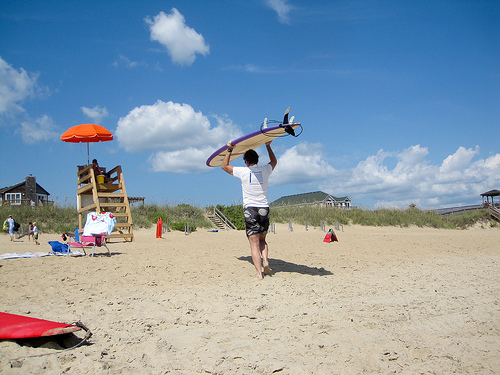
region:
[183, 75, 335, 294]
Man carrying a surf board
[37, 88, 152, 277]
Lifeguard sitting on his stand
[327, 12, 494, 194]
Blue sky with some clouds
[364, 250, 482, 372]
Sandy ground on the beach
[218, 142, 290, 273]
Man wearing tshirt and shorts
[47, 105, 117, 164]
Orange beach umbrella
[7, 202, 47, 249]
A family walking on the beach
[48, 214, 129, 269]
A beach chair sitting on the beach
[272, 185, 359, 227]
A beach house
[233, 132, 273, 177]
A man with dark hair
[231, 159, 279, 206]
man wearing white shirt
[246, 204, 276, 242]
man wearing black shorts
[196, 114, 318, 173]
purple and white surfboard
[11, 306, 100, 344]
red surfboard on sand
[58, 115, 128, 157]
orange umbrella on lifeguard chair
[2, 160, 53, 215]
brown and white home near beach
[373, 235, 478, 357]
tan sand by beach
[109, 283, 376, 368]
tan sand by beach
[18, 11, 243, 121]
white clouds against blue sky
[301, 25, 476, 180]
white clouds against blue sky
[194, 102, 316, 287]
Guy is carrying a surfboard.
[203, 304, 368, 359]
The sand is tan.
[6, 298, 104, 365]
Surfboard on the left side of the picture.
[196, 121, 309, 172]
The surfboard is white and blue.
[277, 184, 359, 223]
A house in the distance.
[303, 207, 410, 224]
The grass is green.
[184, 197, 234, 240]
Steps leaving the beach.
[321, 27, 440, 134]
The sky is blue.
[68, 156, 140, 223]
Lifeguard in the chair.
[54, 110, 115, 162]
The umbrella is orange.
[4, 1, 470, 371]
people on a beach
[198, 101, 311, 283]
man holding a surfboard over his head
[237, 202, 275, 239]
man wearing dark shorts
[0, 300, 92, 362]
part of a red surfboard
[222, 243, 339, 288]
shadow on the sand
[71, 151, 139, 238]
wooden lifeguard post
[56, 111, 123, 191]
large orange umbrella over lifeguard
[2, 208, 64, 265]
people walking in the distance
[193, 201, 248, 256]
stairs leading away from the sand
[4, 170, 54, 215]
building in the distance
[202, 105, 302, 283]
a person carrying a surfboard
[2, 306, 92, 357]
a red surfboard is on the beach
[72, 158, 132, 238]
a wooden life guard chair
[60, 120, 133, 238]
an open umbrella on top of the elevated chair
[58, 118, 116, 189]
the umbrella is above a lifeguard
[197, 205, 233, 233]
stairs go above the dunes on the beach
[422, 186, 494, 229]
a walkway with stairs over the dunes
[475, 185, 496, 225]
a wooden roof over the stairway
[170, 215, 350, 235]
fences holding the sand in place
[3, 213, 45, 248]
people playing on the beach